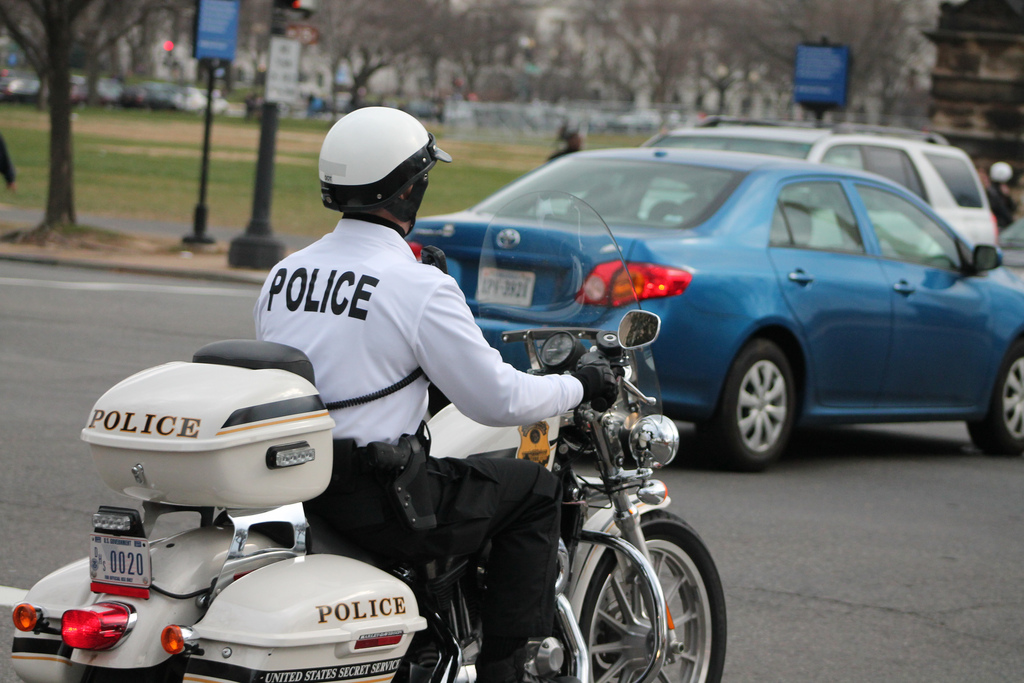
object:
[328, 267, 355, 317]
letter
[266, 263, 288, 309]
letter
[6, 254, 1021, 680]
road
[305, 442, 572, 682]
pants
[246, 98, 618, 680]
police officer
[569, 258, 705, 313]
light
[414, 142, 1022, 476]
car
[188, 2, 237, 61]
sign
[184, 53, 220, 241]
pole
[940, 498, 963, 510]
bad sentence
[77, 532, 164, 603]
license plate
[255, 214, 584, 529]
shirt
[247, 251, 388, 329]
word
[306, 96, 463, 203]
helmet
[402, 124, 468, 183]
visor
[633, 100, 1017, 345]
suv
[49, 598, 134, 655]
lights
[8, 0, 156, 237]
tree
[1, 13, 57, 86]
branches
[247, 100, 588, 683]
cop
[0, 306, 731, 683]
motorcycle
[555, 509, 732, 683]
tire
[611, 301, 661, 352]
mirror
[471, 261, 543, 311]
license plate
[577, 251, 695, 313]
tail light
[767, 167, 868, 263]
window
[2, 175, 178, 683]
street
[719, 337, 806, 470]
tire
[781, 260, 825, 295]
handle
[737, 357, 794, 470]
rim